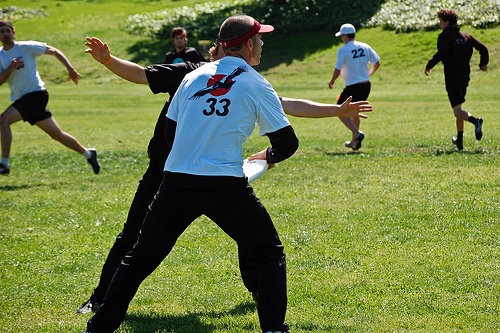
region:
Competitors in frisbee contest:
[5, 8, 496, 245]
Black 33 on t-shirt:
[203, 92, 231, 119]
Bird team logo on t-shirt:
[187, 63, 253, 97]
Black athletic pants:
[83, 171, 299, 327]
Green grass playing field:
[300, 202, 496, 327]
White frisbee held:
[238, 155, 269, 180]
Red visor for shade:
[220, 7, 275, 47]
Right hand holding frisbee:
[240, 133, 288, 183]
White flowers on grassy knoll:
[380, 1, 433, 28]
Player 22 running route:
[327, 19, 382, 150]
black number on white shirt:
[214, 93, 232, 121]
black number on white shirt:
[199, 93, 220, 119]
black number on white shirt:
[347, 47, 359, 59]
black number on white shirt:
[356, 45, 367, 60]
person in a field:
[71, 8, 314, 332]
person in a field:
[321, 17, 383, 156]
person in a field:
[417, 6, 495, 153]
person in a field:
[1, 14, 102, 186]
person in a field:
[154, 21, 203, 68]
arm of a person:
[275, 87, 375, 136]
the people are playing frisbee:
[12, 1, 424, 309]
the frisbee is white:
[222, 142, 296, 209]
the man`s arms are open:
[48, 22, 395, 184]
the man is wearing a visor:
[203, 7, 289, 57]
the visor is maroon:
[198, 4, 283, 50]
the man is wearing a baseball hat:
[315, 10, 383, 49]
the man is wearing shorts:
[312, 79, 394, 166]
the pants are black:
[100, 146, 323, 322]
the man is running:
[0, 10, 111, 190]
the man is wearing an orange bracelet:
[97, 54, 119, 71]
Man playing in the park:
[85, 12, 296, 329]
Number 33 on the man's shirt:
[200, 95, 227, 115]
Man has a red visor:
[215, 17, 275, 44]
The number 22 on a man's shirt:
[350, 47, 365, 53]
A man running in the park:
[0, 18, 100, 174]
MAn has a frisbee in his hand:
[241, 152, 269, 184]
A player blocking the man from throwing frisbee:
[84, 26, 374, 331]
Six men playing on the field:
[0, 8, 498, 331]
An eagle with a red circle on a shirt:
[189, 65, 247, 97]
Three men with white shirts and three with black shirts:
[0, 9, 490, 331]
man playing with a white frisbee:
[173, 11, 304, 327]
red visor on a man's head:
[212, 6, 281, 69]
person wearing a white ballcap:
[324, 16, 385, 151]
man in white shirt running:
[2, 14, 91, 179]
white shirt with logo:
[170, 54, 275, 178]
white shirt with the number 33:
[178, 51, 290, 187]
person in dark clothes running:
[423, 2, 493, 153]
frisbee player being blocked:
[91, 3, 374, 330]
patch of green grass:
[327, 189, 486, 325]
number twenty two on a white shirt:
[329, 42, 386, 88]